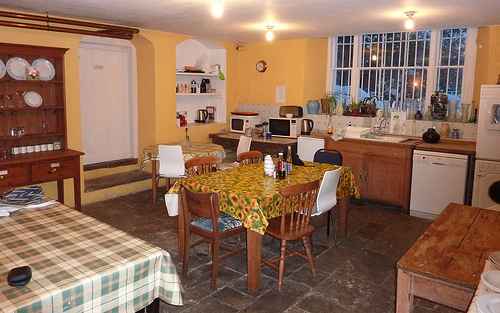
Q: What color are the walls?
A: Yellow.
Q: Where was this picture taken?
A: A kitchen.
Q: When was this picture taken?
A: Night time.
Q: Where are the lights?
A: On the ceiling.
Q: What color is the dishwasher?
A: White.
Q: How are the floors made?
A: Of stone.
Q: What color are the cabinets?
A: Brown.